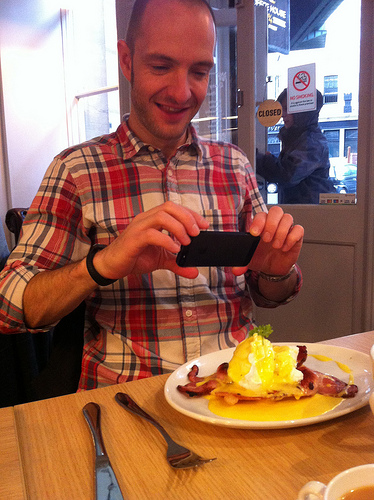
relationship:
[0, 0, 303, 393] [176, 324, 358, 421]
he taking picture of food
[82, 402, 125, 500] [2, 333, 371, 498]
butter knife on table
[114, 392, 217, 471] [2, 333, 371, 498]
fork on table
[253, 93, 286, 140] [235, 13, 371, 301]
sign on door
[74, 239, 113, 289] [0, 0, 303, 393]
wristband on he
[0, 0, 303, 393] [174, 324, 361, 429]
he taking picture of food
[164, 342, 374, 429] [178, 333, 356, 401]
plate of food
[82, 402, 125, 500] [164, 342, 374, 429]
butter knife next to plate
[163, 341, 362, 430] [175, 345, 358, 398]
plate has bacon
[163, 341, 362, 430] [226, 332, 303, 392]
plate has egg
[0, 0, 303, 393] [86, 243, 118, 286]
he has wristband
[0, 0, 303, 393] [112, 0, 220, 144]
he has head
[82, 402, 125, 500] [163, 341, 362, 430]
butter knife beside plate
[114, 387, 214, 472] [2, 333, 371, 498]
fork on table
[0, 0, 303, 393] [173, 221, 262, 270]
he holding h phone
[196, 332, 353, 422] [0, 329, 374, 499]
egg on table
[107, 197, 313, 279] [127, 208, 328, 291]
hands on cellphone hands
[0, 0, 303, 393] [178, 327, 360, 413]
he looking at food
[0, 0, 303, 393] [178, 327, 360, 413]
he smiling at food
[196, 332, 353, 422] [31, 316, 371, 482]
egg with coffee on table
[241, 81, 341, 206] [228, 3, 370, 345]
woman walking into doorway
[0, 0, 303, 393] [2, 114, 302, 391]
he wearing shirt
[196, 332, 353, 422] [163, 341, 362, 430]
egg lying on top of plate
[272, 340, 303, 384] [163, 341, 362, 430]
egg lying on top of plate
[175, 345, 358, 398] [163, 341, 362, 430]
bacon lying on top of plate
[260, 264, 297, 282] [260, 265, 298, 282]
watch worn around wrist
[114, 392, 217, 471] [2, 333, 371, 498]
fork lying on top of table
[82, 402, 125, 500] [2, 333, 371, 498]
butter knife lying on top of table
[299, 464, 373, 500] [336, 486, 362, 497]
coffee containing tea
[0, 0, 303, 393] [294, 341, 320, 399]
he photographing bacon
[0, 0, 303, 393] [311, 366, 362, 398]
he photographing bacon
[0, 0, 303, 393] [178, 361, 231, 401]
he photographing bacon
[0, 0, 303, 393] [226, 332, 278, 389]
he photographing egg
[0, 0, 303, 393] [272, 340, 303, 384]
he photographing egg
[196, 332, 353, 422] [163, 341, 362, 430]
egg on plate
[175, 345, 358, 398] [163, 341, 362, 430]
bacon on plate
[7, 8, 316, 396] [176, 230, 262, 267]
he has phone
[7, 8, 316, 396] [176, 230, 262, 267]
he taking photo with phone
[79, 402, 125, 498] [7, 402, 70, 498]
butter knife on table